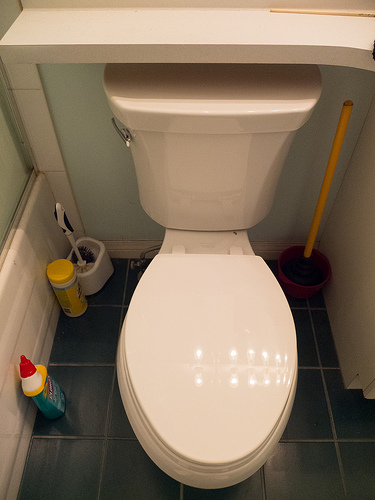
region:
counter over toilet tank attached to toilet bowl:
[6, 8, 366, 493]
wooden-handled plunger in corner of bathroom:
[278, 77, 356, 300]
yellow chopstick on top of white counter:
[261, 7, 373, 69]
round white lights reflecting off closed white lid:
[184, 340, 293, 388]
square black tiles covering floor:
[18, 241, 368, 494]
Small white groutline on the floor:
[303, 302, 315, 320]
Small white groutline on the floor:
[309, 315, 325, 356]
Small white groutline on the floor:
[318, 360, 339, 376]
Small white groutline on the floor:
[319, 370, 337, 438]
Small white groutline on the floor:
[334, 433, 374, 454]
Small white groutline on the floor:
[334, 438, 358, 498]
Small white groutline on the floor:
[90, 433, 106, 497]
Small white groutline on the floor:
[30, 424, 123, 451]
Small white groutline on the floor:
[49, 356, 109, 377]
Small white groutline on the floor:
[112, 254, 129, 318]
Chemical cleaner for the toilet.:
[15, 352, 70, 424]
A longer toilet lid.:
[122, 252, 301, 468]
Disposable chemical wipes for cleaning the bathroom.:
[45, 258, 88, 318]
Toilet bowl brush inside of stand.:
[54, 202, 115, 296]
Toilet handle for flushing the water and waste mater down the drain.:
[108, 116, 134, 149]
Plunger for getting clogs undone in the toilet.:
[276, 100, 353, 300]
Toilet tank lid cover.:
[101, 62, 322, 135]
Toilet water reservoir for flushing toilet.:
[101, 63, 323, 231]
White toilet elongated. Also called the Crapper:
[102, 62, 323, 491]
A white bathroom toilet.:
[37, 46, 358, 499]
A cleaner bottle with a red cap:
[19, 353, 64, 421]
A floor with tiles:
[15, 257, 373, 499]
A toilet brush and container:
[54, 201, 111, 296]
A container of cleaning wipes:
[45, 258, 88, 318]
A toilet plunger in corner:
[278, 101, 354, 297]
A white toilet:
[103, 65, 322, 488]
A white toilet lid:
[122, 251, 297, 465]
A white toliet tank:
[103, 64, 324, 232]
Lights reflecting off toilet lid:
[182, 344, 293, 386]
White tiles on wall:
[0, 0, 86, 235]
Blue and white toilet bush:
[49, 201, 107, 277]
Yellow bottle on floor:
[45, 259, 85, 332]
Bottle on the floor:
[11, 340, 69, 424]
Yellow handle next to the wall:
[316, 87, 352, 276]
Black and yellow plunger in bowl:
[267, 236, 330, 304]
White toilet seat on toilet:
[120, 242, 294, 452]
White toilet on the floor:
[80, 67, 303, 492]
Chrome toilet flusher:
[99, 112, 145, 150]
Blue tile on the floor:
[319, 364, 369, 444]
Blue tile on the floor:
[335, 442, 373, 488]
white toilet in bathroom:
[78, 103, 316, 459]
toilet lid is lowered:
[133, 268, 303, 448]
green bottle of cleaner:
[9, 355, 94, 454]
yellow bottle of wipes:
[52, 257, 93, 322]